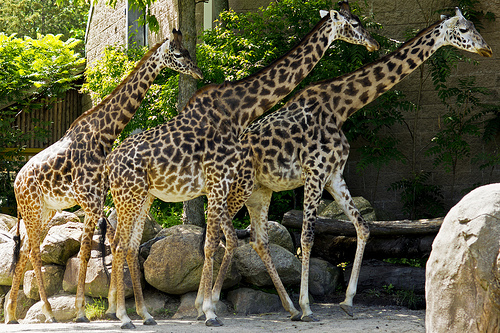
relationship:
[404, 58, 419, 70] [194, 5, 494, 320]
spot on giraffe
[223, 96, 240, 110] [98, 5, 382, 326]
spot on giraffe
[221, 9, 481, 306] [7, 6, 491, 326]
giraffe in a line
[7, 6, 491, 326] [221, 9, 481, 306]
line of giraffe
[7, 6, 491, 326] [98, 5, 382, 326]
line of giraffe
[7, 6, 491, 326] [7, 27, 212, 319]
line of giraffe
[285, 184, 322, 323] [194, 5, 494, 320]
leg of giraffe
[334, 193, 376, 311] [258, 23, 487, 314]
leg of giraffe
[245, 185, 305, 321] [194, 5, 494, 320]
leg of giraffe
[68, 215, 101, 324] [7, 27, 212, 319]
leg of giraffe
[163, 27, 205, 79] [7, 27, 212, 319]
head of giraffe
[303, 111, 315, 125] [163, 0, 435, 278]
spot on giraffe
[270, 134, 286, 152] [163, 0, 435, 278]
spot on giraffe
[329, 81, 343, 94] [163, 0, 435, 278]
spot on giraffe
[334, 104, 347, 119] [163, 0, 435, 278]
spot on giraffe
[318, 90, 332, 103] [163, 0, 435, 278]
spot on giraffe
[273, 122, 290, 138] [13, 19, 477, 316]
spot on giraffes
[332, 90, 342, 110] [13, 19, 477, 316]
spot on giraffes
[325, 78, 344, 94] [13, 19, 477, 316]
spot on giraffes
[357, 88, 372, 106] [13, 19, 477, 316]
spot on giraffes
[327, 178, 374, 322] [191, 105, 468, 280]
leg of giraffe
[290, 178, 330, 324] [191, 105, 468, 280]
leg of giraffe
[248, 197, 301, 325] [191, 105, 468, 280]
leg of giraffe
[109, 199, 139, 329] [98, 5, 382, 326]
leg of giraffe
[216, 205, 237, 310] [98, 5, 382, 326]
leg of giraffe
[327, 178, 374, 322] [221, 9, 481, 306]
leg of giraffe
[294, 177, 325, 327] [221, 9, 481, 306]
leg of giraffe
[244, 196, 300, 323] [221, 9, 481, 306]
leg of giraffe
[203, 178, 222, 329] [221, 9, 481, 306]
leg of giraffe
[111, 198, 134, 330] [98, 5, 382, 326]
leg of giraffe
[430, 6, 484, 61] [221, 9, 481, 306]
head of giraffe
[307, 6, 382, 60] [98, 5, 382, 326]
head of giraffe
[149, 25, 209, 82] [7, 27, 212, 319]
head of giraffe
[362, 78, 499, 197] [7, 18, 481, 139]
wall in background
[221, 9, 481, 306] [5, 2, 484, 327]
giraffe at a zoo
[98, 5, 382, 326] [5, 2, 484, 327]
giraffe at a zoo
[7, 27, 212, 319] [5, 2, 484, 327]
giraffe at a zoo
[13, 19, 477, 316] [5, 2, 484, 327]
giraffes at a zoo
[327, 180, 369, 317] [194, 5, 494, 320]
leg of a giraffe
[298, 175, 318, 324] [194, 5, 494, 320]
leg of a giraffe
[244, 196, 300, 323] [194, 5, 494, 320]
leg of a giraffe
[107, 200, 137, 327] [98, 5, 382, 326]
leg of a giraffe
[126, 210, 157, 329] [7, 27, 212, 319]
leg of a giraffe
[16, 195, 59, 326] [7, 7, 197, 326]
leg of a giraffe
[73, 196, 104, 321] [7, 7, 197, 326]
leg of a giraffe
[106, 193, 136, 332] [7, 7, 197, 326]
leg of a giraffe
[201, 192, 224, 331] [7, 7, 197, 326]
leg of a giraffe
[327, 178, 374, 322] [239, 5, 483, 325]
leg of a giraffe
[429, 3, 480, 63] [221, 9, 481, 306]
head of a giraffe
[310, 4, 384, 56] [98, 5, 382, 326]
head of a giraffe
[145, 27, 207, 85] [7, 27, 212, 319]
head of a giraffe